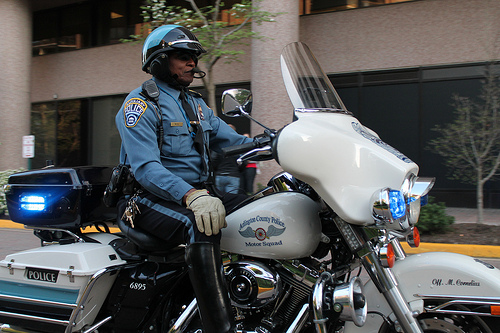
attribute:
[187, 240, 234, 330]
boot — black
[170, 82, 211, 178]
tie — black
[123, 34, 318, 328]
officer — seated 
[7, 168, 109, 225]
case — black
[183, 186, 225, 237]
glove — white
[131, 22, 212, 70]
helmet — blue, black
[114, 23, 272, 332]
motorcycle — white, police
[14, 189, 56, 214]
light — blue, police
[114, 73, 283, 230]
shirt — blue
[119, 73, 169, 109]
radio — black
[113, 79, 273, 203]
shirt — long sleeve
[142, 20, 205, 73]
helmet — black, blue, police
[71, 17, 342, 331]
cop — black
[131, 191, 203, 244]
blue stripe — light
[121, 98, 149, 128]
patch — uniform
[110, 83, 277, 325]
uniform — police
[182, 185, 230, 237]
glove — gray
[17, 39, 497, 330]
motorcycle — white